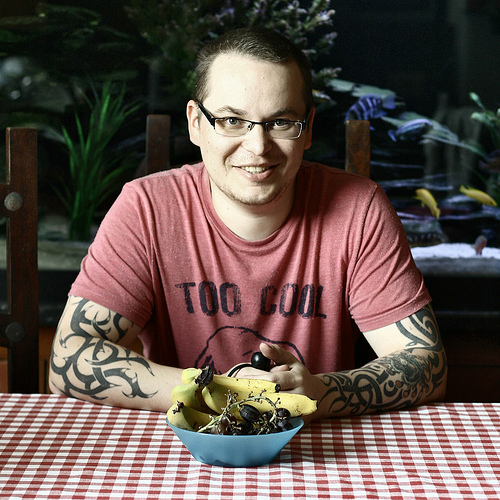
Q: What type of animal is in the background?
A: Fish.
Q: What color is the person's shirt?
A: Red.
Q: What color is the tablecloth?
A: Red and white.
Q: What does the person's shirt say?
A: Too cool.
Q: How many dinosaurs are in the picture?
A: Zero.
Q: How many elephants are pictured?
A: Zero.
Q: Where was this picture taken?
A: In front of a large aquarium.